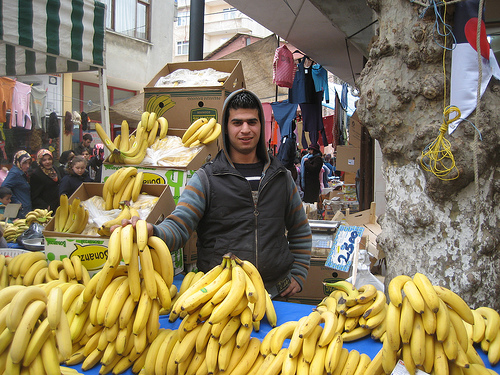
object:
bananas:
[103, 167, 144, 210]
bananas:
[97, 202, 140, 236]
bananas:
[95, 120, 148, 164]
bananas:
[0, 209, 53, 243]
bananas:
[97, 163, 147, 209]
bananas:
[54, 194, 90, 233]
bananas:
[142, 136, 202, 166]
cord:
[420, 0, 482, 181]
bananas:
[361, 273, 474, 375]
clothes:
[273, 44, 297, 88]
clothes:
[288, 55, 307, 104]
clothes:
[312, 63, 330, 103]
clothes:
[332, 83, 349, 145]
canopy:
[219, 0, 375, 87]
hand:
[110, 215, 153, 237]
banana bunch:
[95, 220, 173, 311]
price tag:
[324, 225, 365, 272]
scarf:
[300, 153, 313, 187]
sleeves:
[150, 168, 206, 252]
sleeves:
[283, 168, 311, 287]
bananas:
[0, 220, 499, 373]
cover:
[53, 273, 500, 375]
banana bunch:
[24, 209, 52, 227]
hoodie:
[149, 88, 312, 293]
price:
[338, 231, 358, 262]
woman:
[30, 149, 61, 216]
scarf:
[32, 149, 58, 182]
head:
[37, 149, 53, 169]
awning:
[0, 0, 106, 75]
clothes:
[29, 86, 48, 133]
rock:
[356, 0, 499, 317]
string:
[356, 0, 452, 160]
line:
[283, 0, 305, 41]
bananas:
[75, 265, 177, 374]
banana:
[169, 252, 277, 373]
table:
[2, 282, 482, 372]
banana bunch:
[102, 218, 152, 270]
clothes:
[9, 81, 32, 130]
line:
[41, 89, 100, 106]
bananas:
[136, 111, 168, 147]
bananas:
[182, 118, 222, 148]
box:
[103, 127, 222, 170]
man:
[110, 89, 312, 302]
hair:
[226, 91, 260, 110]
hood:
[222, 89, 271, 171]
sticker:
[200, 287, 208, 292]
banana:
[179, 271, 204, 295]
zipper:
[254, 209, 259, 215]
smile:
[235, 129, 258, 143]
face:
[228, 108, 261, 153]